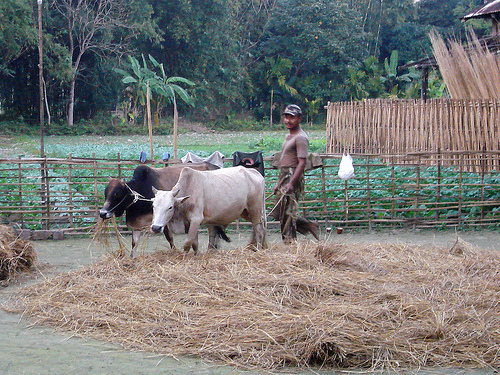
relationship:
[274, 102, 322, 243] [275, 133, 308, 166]
man wearing shirt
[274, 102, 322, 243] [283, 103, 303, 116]
man wearing hat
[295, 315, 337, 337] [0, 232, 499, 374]
straw on ground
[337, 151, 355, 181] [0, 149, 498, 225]
bag on fence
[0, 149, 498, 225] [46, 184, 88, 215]
fence in front of crop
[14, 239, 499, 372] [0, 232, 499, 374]
pile of hay on ground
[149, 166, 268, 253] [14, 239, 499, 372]
cow walking behind pile of hay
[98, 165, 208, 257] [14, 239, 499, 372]
cow walking behind pile of hay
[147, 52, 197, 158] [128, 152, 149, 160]
palm tree in crop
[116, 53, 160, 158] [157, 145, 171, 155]
palm tree in crop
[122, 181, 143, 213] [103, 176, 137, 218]
rope tied on cow's neck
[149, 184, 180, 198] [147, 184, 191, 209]
horns on cow's head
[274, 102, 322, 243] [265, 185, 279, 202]
man holding stick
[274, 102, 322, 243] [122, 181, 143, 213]
man holding rope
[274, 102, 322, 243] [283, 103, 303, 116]
man with hat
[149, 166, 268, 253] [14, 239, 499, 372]
cow eating pile of hay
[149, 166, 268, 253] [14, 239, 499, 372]
cow standing on pile of hay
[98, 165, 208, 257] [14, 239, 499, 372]
cow eating pile of hay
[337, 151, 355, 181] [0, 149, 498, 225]
bag hanging on fence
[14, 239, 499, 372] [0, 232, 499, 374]
pile of hay lying on ground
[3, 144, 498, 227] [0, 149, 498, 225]
vegetable garden behind fence